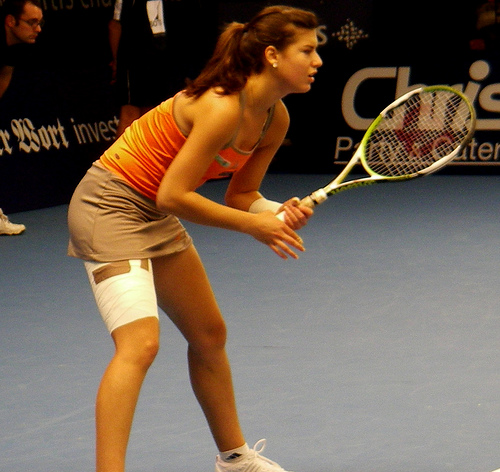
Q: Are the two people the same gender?
A: No, they are both male and female.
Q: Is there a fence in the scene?
A: No, there are no fences.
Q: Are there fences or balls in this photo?
A: No, there are no fences or balls.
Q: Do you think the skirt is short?
A: Yes, the skirt is short.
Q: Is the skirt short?
A: Yes, the skirt is short.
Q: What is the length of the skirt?
A: The skirt is short.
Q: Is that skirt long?
A: No, the skirt is short.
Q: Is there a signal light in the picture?
A: No, there are no traffic lights.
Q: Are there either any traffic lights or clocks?
A: No, there are no traffic lights or clocks.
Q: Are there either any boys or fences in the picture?
A: No, there are no boys or fences.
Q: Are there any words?
A: Yes, there are words.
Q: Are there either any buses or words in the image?
A: Yes, there are words.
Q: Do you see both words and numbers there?
A: No, there are words but no numbers.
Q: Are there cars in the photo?
A: No, there are no cars.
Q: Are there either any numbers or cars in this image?
A: No, there are no cars or numbers.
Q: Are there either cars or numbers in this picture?
A: No, there are no cars or numbers.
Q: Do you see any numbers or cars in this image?
A: No, there are no cars or numbers.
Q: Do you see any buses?
A: No, there are no buses.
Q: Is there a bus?
A: No, there are no buses.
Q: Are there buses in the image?
A: No, there are no buses.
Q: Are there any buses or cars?
A: No, there are no buses or cars.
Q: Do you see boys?
A: No, there are no boys.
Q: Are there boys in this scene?
A: No, there are no boys.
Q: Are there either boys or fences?
A: No, there are no fences or boys.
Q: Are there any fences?
A: No, there are no fences.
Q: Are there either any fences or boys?
A: No, there are no fences or boys.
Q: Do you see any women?
A: Yes, there is a woman.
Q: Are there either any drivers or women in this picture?
A: Yes, there is a woman.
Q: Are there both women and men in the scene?
A: Yes, there are both a woman and a man.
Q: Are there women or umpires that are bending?
A: Yes, the woman is bending.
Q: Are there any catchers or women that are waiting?
A: Yes, the woman is waiting.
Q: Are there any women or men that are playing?
A: Yes, the woman is playing.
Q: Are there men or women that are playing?
A: Yes, the woman is playing.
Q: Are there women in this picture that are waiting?
A: Yes, there is a woman that is waiting.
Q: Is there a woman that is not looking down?
A: Yes, there is a woman that is waiting.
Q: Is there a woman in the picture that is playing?
A: Yes, there is a woman that is playing.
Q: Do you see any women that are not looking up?
A: Yes, there is a woman that is playing .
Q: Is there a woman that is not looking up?
A: Yes, there is a woman that is playing.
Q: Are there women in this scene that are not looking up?
A: Yes, there is a woman that is playing.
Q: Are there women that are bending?
A: Yes, there is a woman that is bending.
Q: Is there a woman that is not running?
A: Yes, there is a woman that is bending.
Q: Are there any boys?
A: No, there are no boys.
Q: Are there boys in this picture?
A: No, there are no boys.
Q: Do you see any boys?
A: No, there are no boys.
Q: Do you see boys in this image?
A: No, there are no boys.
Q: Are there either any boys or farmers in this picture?
A: No, there are no boys or farmers.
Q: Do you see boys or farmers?
A: No, there are no boys or farmers.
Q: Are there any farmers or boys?
A: No, there are no boys or farmers.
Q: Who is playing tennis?
A: The woman is playing tennis.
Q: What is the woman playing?
A: The woman is playing tennis.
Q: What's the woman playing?
A: The woman is playing tennis.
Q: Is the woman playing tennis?
A: Yes, the woman is playing tennis.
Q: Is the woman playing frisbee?
A: No, the woman is playing tennis.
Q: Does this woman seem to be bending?
A: Yes, the woman is bending.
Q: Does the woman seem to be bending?
A: Yes, the woman is bending.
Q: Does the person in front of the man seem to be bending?
A: Yes, the woman is bending.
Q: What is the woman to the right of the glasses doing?
A: The woman is bending.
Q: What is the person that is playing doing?
A: The woman is bending.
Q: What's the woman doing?
A: The woman is bending.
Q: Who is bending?
A: The woman is bending.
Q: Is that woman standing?
A: No, the woman is bending.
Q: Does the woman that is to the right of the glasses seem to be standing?
A: No, the woman is bending.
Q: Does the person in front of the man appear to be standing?
A: No, the woman is bending.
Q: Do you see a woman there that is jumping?
A: No, there is a woman but she is bending.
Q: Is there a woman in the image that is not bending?
A: No, there is a woman but she is bending.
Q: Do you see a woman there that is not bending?
A: No, there is a woman but she is bending.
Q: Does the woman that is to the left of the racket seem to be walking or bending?
A: The woman is bending.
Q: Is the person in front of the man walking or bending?
A: The woman is bending.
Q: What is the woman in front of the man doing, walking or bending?
A: The woman is bending.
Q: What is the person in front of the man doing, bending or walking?
A: The woman is bending.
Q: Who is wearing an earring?
A: The woman is wearing an earring.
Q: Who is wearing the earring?
A: The woman is wearing an earring.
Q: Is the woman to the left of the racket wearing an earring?
A: Yes, the woman is wearing an earring.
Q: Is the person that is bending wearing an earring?
A: Yes, the woman is wearing an earring.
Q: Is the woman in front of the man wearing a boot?
A: No, the woman is wearing an earring.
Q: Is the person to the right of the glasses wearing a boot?
A: No, the woman is wearing an earring.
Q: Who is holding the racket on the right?
A: The woman is holding the tennis racket.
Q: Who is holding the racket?
A: The woman is holding the tennis racket.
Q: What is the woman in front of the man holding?
A: The woman is holding the racket.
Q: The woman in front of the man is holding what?
A: The woman is holding the racket.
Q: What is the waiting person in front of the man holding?
A: The woman is holding the racket.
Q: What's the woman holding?
A: The woman is holding the racket.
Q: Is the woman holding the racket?
A: Yes, the woman is holding the racket.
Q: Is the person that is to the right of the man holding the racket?
A: Yes, the woman is holding the racket.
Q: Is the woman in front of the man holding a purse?
A: No, the woman is holding the racket.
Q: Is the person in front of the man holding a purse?
A: No, the woman is holding the racket.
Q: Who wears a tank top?
A: The woman wears a tank top.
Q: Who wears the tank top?
A: The woman wears a tank top.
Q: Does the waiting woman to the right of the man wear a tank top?
A: Yes, the woman wears a tank top.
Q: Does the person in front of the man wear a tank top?
A: Yes, the woman wears a tank top.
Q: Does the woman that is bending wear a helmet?
A: No, the woman wears a tank top.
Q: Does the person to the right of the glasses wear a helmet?
A: No, the woman wears a tank top.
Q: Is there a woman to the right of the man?
A: Yes, there is a woman to the right of the man.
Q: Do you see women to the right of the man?
A: Yes, there is a woman to the right of the man.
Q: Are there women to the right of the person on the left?
A: Yes, there is a woman to the right of the man.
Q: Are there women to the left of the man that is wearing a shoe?
A: No, the woman is to the right of the man.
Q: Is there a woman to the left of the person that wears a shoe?
A: No, the woman is to the right of the man.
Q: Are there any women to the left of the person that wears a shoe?
A: No, the woman is to the right of the man.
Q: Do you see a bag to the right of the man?
A: No, there is a woman to the right of the man.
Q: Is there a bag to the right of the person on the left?
A: No, there is a woman to the right of the man.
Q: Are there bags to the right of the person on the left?
A: No, there is a woman to the right of the man.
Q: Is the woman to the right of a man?
A: Yes, the woman is to the right of a man.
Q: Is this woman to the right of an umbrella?
A: No, the woman is to the right of a man.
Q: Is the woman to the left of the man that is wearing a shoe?
A: No, the woman is to the right of the man.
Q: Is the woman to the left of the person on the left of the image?
A: No, the woman is to the right of the man.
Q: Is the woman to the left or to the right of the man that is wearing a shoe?
A: The woman is to the right of the man.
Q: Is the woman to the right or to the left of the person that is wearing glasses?
A: The woman is to the right of the man.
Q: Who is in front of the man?
A: The woman is in front of the man.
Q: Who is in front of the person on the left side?
A: The woman is in front of the man.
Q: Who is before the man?
A: The woman is in front of the man.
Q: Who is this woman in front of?
A: The woman is in front of the man.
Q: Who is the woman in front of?
A: The woman is in front of the man.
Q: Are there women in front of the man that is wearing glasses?
A: Yes, there is a woman in front of the man.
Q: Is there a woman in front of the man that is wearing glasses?
A: Yes, there is a woman in front of the man.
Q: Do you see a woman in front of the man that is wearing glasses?
A: Yes, there is a woman in front of the man.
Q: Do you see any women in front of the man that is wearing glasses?
A: Yes, there is a woman in front of the man.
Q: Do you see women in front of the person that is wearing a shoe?
A: Yes, there is a woman in front of the man.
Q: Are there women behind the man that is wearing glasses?
A: No, the woman is in front of the man.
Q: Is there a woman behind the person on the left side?
A: No, the woman is in front of the man.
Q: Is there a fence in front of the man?
A: No, there is a woman in front of the man.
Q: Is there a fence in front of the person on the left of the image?
A: No, there is a woman in front of the man.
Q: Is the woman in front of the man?
A: Yes, the woman is in front of the man.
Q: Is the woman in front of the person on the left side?
A: Yes, the woman is in front of the man.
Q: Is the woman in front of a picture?
A: No, the woman is in front of the man.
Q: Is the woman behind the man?
A: No, the woman is in front of the man.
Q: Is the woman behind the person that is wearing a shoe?
A: No, the woman is in front of the man.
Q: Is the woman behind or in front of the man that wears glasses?
A: The woman is in front of the man.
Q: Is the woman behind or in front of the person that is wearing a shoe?
A: The woman is in front of the man.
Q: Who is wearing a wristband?
A: The woman is wearing a wristband.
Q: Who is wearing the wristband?
A: The woman is wearing a wristband.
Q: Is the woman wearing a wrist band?
A: Yes, the woman is wearing a wrist band.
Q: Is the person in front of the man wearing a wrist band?
A: Yes, the woman is wearing a wrist band.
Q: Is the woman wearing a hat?
A: No, the woman is wearing a wrist band.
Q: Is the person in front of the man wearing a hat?
A: No, the woman is wearing a wrist band.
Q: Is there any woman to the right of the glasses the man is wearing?
A: Yes, there is a woman to the right of the glasses.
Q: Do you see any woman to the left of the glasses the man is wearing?
A: No, the woman is to the right of the glasses.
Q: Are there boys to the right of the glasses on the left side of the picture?
A: No, there is a woman to the right of the glasses.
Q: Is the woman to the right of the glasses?
A: Yes, the woman is to the right of the glasses.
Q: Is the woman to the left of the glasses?
A: No, the woman is to the right of the glasses.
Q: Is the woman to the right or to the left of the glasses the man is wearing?
A: The woman is to the right of the glasses.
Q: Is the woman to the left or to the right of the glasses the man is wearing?
A: The woman is to the right of the glasses.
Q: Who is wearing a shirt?
A: The woman is wearing a shirt.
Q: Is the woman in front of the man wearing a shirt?
A: Yes, the woman is wearing a shirt.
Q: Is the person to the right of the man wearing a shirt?
A: Yes, the woman is wearing a shirt.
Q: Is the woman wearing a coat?
A: No, the woman is wearing a shirt.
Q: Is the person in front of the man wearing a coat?
A: No, the woman is wearing a shirt.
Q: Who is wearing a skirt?
A: The woman is wearing a skirt.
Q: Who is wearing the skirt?
A: The woman is wearing a skirt.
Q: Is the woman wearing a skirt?
A: Yes, the woman is wearing a skirt.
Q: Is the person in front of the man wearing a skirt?
A: Yes, the woman is wearing a skirt.